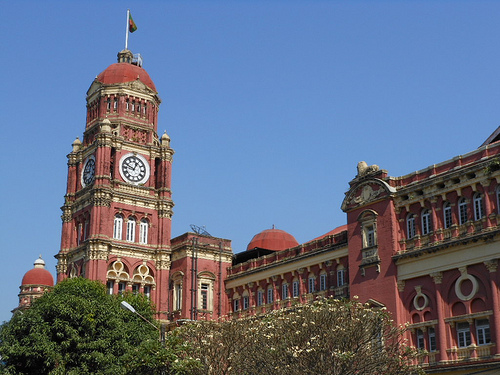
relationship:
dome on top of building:
[241, 223, 301, 258] [231, 220, 374, 302]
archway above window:
[411, 312, 420, 322] [402, 310, 484, 345]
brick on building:
[381, 225, 392, 235] [17, 9, 498, 373]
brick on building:
[380, 294, 392, 304] [17, 9, 498, 373]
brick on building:
[364, 285, 374, 293] [17, 9, 498, 373]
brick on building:
[350, 274, 361, 281] [17, 9, 498, 373]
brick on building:
[348, 241, 360, 249] [17, 9, 498, 373]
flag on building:
[116, 8, 141, 54] [52, 8, 177, 335]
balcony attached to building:
[450, 343, 496, 363] [230, 131, 498, 361]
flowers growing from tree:
[150, 287, 427, 369] [197, 328, 387, 363]